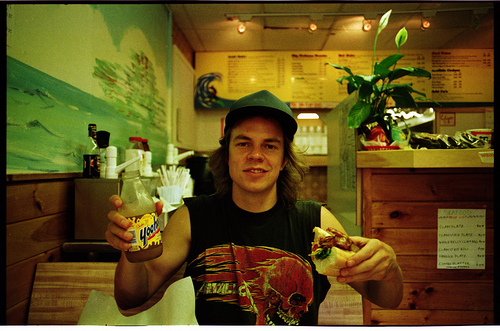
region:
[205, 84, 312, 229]
a man wearing a green hat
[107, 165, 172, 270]
a bottle of yoohoo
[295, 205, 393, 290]
a sandwich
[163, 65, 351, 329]
a shirt with a red skull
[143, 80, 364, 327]
a man wearing a green baseball cap and a black shirt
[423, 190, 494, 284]
a paper that is hand written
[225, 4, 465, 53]
a line of four lights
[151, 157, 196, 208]
a cup with a lot of straws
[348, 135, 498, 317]
a counter made of two different kinds of wood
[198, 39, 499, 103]
a long menu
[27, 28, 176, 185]
The wall is painted like an ocean.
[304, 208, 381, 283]
The man is holding a sandwich.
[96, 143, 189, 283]
The man is also holding chocolate milk.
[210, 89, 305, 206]
The man has long hair.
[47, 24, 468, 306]
this is a restaurant.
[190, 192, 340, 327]
The man has a tank top on.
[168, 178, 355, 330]
The tank top is black.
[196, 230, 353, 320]
The tank top has a skull on it.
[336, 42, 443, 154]
This is a green plant.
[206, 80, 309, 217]
The man is smiling.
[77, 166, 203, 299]
Man is holding a yoohoo bottle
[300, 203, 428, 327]
Man holding sandwich in his hand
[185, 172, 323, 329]
The shirt is black with a red skull on it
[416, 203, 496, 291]
Piece of paper hanging on the wall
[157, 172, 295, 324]
The shirt has no sleeves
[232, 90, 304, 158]
Man is wearing a hat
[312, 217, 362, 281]
Sandwich has sauce on it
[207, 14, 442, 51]
Lights on the ceiling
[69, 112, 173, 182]
Coffee stuff on counter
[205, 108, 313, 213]
The man is smiling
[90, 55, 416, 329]
a guy holding a drink and a sandwich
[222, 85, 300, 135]
a baseball cap the guy is wearing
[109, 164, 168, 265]
a drink a guy is holding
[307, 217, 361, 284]
a delicious food the guy is holding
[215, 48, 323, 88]
menu in the background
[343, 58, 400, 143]
a pot of plant in the background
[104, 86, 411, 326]
a guy in a fastfood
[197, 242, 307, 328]
a print on the guy's shirt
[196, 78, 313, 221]
a guy with a long hair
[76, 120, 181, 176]
condiments on the side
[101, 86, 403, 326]
young man holding a Yoohoo drink and a sandwich in a restaurant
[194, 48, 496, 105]
wall menu at a restaurant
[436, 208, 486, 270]
written menu hanging on restaurant counter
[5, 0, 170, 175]
mural depicting the ocean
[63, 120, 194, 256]
restaurant condiment stand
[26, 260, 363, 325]
table bench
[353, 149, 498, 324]
restaurant counter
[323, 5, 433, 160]
green indoor plant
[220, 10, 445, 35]
line of lights on ceiling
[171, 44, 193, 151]
plaint white wall